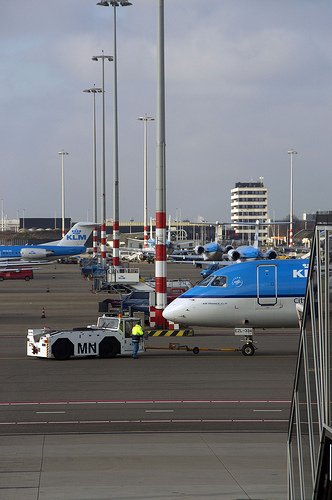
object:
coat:
[132, 323, 144, 343]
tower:
[230, 177, 269, 241]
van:
[0, 265, 33, 282]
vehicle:
[26, 313, 145, 361]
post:
[155, 0, 167, 311]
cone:
[41, 305, 46, 319]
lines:
[56, 397, 190, 423]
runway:
[0, 354, 323, 437]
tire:
[242, 343, 255, 356]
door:
[258, 267, 277, 306]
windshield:
[199, 276, 226, 287]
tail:
[58, 222, 102, 246]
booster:
[20, 247, 47, 258]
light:
[119, 313, 122, 318]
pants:
[132, 342, 139, 357]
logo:
[67, 228, 86, 240]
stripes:
[15, 399, 263, 425]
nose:
[161, 286, 200, 326]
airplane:
[162, 259, 309, 356]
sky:
[180, 10, 316, 128]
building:
[230, 177, 268, 241]